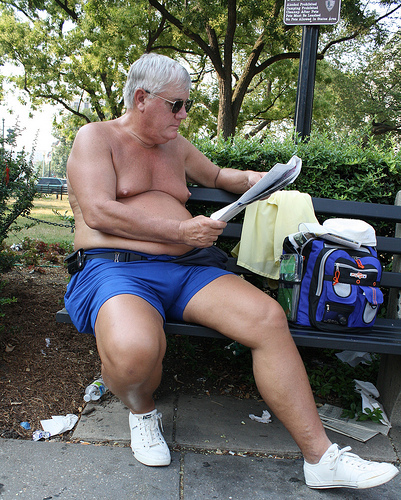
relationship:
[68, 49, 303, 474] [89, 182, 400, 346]
man on bench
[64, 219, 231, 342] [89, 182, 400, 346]
sitting on bench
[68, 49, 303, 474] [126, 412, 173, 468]
man wearing shoes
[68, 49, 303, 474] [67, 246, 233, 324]
man wearing shorts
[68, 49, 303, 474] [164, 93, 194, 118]
man wearing sunglasses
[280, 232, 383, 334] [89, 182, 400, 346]
bag on bench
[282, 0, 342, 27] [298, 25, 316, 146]
sign on poll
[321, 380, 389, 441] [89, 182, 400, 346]
trash under bench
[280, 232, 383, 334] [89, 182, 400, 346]
backpack on bench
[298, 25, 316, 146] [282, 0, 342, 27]
pole holding sign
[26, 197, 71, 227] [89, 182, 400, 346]
grass behind bench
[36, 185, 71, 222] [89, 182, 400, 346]
field behind bench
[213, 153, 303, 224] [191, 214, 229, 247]
newspaper in hand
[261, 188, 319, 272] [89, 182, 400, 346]
draped over bench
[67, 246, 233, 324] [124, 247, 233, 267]
shorts and fanny pack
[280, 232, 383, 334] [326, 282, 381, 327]
bag has pockets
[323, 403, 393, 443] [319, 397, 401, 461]
newspaper on ground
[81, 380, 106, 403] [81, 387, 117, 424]
water bottle on ground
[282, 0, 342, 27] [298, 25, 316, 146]
sign on pole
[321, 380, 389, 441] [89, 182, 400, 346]
litter beneath bench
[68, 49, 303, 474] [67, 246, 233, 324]
man in shorts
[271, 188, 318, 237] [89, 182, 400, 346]
shirt on bench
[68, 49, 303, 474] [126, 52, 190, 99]
man with hair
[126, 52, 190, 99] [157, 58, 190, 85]
hair combed forward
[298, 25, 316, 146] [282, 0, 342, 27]
signpost and sign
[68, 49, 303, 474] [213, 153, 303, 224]
man reading paper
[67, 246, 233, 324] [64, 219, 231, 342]
pair of blue shorts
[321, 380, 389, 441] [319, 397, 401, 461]
paper on ground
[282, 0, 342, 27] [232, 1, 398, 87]
sign in park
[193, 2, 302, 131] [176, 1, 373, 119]
tree in background